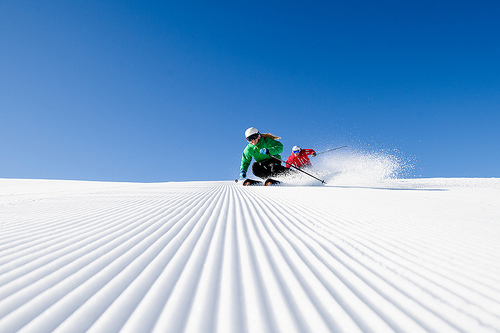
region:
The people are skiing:
[213, 109, 335, 202]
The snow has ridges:
[35, 125, 455, 320]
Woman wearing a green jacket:
[225, 113, 330, 202]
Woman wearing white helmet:
[232, 122, 284, 173]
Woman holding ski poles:
[214, 100, 320, 205]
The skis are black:
[237, 173, 296, 197]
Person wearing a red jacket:
[280, 132, 330, 202]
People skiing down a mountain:
[215, 111, 367, 211]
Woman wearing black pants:
[227, 112, 333, 232]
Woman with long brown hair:
[224, 120, 308, 187]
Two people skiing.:
[227, 115, 330, 195]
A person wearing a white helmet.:
[240, 127, 262, 139]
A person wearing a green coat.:
[235, 140, 280, 172]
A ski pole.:
[280, 160, 320, 176]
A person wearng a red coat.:
[285, 145, 305, 165]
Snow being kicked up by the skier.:
[290, 135, 400, 180]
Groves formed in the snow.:
[146, 190, 396, 325]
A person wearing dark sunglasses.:
[240, 127, 260, 144]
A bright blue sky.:
[140, 35, 371, 116]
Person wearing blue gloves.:
[256, 142, 268, 153]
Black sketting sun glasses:
[246, 136, 263, 141]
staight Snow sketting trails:
[136, 196, 298, 306]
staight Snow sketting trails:
[24, 220, 104, 321]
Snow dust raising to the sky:
[313, 148, 402, 190]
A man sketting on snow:
[236, 129, 286, 188]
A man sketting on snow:
[287, 143, 322, 178]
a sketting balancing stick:
[261, 146, 322, 183]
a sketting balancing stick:
[312, 143, 347, 154]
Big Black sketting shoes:
[246, 176, 277, 189]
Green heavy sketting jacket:
[240, 141, 289, 160]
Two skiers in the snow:
[223, 110, 353, 196]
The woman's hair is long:
[245, 126, 281, 141]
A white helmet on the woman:
[245, 121, 265, 136]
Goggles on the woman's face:
[245, 132, 260, 139]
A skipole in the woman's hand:
[255, 152, 329, 187]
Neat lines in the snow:
[72, 189, 191, 304]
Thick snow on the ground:
[41, 221, 393, 319]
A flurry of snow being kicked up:
[282, 147, 394, 188]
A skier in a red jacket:
[284, 149, 317, 173]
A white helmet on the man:
[290, 146, 303, 151]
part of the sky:
[114, 27, 172, 132]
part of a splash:
[371, 163, 411, 213]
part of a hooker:
[289, 148, 333, 192]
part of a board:
[236, 135, 300, 205]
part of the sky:
[421, 132, 458, 169]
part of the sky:
[133, 80, 184, 189]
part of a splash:
[343, 124, 397, 206]